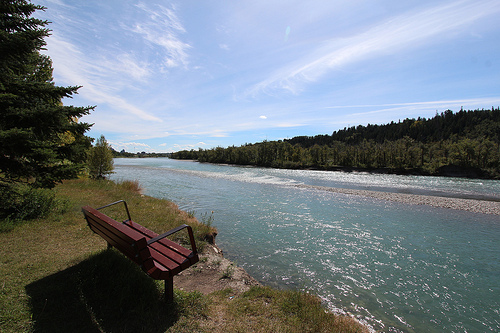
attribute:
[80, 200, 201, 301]
bench — red, empty, brown, curved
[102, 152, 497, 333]
water — serene, a river, clear blue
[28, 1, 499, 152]
sky — blue, peaceful, bright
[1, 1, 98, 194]
tree — green, large, pine, pine tree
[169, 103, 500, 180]
hill — small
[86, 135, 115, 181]
shrub — small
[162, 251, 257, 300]
patch — small